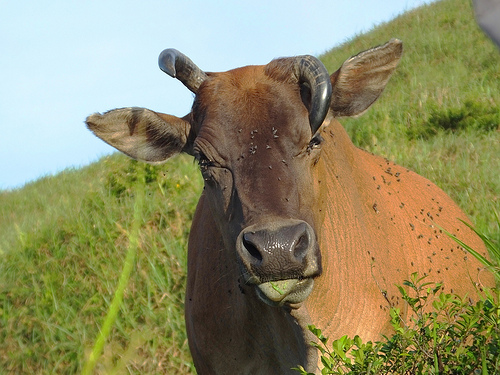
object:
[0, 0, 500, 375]
grass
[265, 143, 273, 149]
files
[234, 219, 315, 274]
nose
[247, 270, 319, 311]
mouth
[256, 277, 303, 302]
bull's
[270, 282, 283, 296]
grass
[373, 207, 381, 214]
files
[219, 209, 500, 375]
front of bull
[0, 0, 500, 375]
field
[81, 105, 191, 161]
ears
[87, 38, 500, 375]
brown cow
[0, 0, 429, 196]
bright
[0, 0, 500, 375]
day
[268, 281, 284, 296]
food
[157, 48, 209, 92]
black horns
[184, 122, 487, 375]
body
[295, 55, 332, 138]
cow's horn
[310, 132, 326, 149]
eye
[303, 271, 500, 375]
bush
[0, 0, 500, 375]
hillside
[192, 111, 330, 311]
face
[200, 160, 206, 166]
flies in eye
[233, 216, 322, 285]
cow's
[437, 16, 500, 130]
on grassy hill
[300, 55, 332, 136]
and black